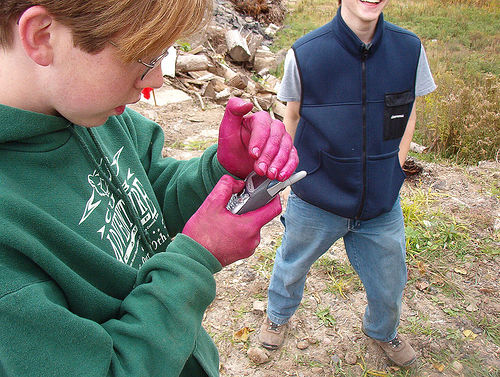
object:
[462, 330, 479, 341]
brown leaves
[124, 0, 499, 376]
ground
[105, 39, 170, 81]
glasses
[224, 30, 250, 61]
log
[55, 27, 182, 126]
face